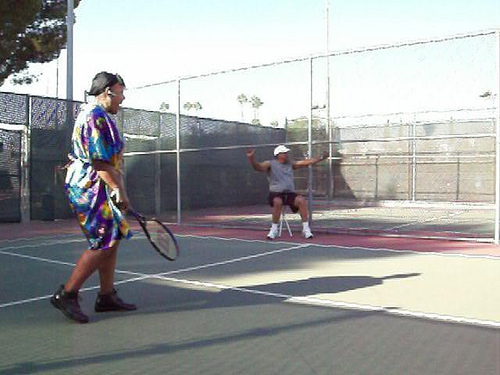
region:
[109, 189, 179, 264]
Tennis racket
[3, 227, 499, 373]
Tennis court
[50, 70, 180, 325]
Tennis player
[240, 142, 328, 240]
Spectator at a tennis match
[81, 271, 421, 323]
shaddow of a tennis player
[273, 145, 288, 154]
white baseball hat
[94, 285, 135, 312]
black athletic shoe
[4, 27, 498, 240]
Fence that surrounds a tennis court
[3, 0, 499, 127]
clear light blue sky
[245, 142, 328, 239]
Man in a gray tank top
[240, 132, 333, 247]
A man sitting on a stool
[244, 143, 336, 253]
A man wearing a white cap and white tennis shoes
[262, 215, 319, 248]
White tennis shoes with socks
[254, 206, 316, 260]
White tennis shoes with white socks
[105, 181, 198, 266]
Tennis racket in a hand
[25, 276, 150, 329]
Black shoes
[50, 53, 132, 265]
A lady wearing a dress with print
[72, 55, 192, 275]
A lady holding a tennis racket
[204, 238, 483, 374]
A person's shadow on a tennis court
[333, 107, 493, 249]
A wired fence on the side of a tennis court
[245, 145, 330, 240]
man in white hat sitting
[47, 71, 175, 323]
woman in floral dress holding racket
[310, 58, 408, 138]
metal chain link fence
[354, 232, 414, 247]
red ground of tennis court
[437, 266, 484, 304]
green ground of tennis court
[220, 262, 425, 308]
shadow of woman on court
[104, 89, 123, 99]
bluetooth phone piece in persons ear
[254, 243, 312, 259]
white line on green tennis court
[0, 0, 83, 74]
green tree over tennis court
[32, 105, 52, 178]
plastic privacy slats on fence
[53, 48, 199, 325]
a woman with racket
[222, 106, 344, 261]
man sitting on a chair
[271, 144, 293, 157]
a white baseball cap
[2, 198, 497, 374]
part of a tennis court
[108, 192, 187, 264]
a large tennis racket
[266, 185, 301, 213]
a man's shorts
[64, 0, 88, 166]
a long gray pole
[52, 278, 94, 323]
a man's black tennis shoe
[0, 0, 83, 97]
part of a green tree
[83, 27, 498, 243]
a large chain link fence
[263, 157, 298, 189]
a man's gray tank top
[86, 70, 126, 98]
a man's black hair